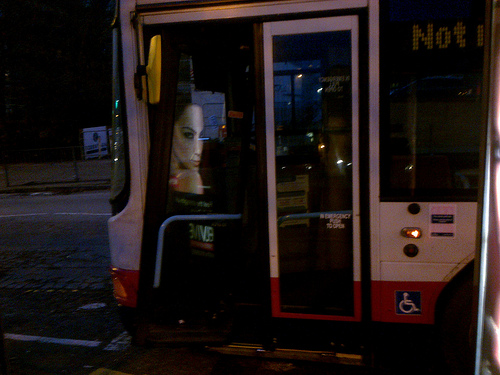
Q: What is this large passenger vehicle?
A: Bus.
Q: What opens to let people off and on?
A: Doors.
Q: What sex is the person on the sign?
A: Female.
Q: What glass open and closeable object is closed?
A: Door.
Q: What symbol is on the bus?
A: A handicap Symbol.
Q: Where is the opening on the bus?
A: The door.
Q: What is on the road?
A: The bus.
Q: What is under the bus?
A: The road.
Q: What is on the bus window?
A: A reflection.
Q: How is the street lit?
A: Dimly.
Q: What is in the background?
A: A fence.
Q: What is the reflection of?
A: A woman.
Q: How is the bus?
A: Empty.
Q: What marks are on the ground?
A: Road markings.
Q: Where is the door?
A: The front left side of a transit bus.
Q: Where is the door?
A: The left side of the transit bus.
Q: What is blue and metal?
A: Rods on the transit bus.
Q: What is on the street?
A: A red and white bus.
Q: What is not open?
A: The bus door.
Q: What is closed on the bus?
A: The bus door.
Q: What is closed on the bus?
A: The door.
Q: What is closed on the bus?
A: The doors.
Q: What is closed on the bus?
A: The bus doors.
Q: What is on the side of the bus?
A: A mirror.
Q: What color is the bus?
A: Red and white.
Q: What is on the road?
A: The bus.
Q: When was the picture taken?
A: At night.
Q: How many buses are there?
A: One.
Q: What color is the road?
A: Black.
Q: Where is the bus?
A: On the road.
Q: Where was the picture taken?
A: On the street.